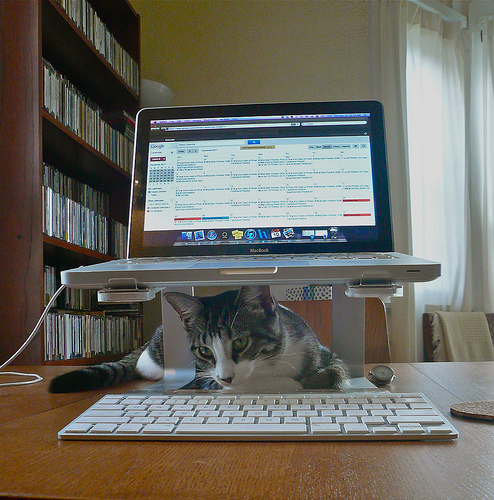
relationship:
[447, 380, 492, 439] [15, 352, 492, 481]
coaster on table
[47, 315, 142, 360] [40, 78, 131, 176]
books on shelf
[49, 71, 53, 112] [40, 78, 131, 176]
books on shelf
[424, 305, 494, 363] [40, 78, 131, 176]
blanket on shelf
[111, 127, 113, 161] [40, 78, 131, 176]
books on shelf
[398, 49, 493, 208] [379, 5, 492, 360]
white curtain on windows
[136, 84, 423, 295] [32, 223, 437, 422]
computer on desk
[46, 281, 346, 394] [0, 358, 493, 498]
cat laying on desk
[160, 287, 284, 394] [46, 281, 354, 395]
face on cat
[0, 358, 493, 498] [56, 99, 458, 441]
desk under computer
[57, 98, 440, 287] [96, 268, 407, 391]
laptop sitting on stand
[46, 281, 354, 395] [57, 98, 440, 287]
cat sitting underneath laptop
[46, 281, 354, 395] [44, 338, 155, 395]
cat has tail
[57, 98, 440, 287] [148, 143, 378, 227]
laptop using calendar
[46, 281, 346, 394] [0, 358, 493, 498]
cat sitting on desk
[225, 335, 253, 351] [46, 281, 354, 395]
eye of cat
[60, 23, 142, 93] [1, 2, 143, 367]
books on bookshelf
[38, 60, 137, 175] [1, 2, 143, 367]
books on bookshelf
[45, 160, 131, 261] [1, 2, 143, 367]
books on bookshelf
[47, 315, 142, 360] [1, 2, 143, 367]
books on bookshelf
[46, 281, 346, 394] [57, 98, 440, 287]
cat under laptop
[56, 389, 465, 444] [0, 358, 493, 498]
keyboard on desk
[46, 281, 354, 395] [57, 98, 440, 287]
cat underneath laptop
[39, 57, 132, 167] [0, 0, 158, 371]
books on bookshelf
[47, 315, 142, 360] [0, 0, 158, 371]
books on bookshelf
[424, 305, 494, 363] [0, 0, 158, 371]
blanket on bookshelf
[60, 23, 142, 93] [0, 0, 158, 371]
books on bookshelf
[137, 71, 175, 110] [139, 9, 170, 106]
lamp in corner